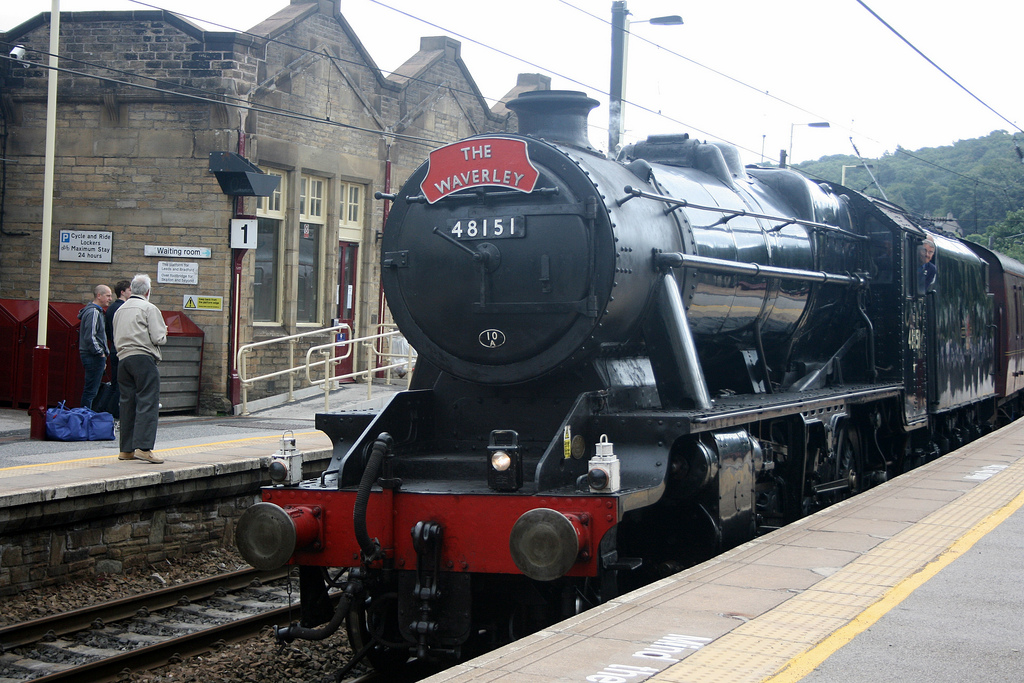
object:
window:
[250, 219, 278, 323]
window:
[295, 221, 323, 324]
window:
[339, 184, 359, 222]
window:
[299, 177, 324, 217]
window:
[255, 169, 285, 211]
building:
[0, 0, 550, 418]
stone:
[20, 535, 48, 564]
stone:
[65, 531, 97, 553]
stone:
[104, 519, 126, 534]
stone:
[128, 509, 148, 539]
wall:
[0, 446, 332, 598]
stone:
[165, 510, 200, 519]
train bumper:
[236, 487, 619, 582]